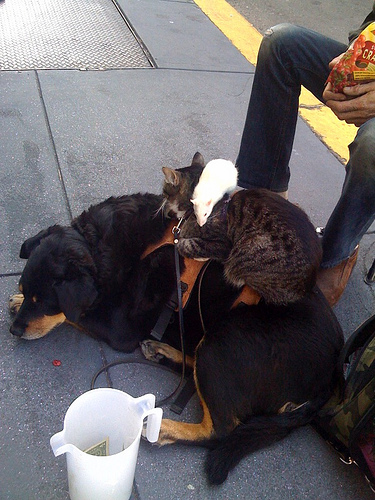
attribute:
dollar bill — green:
[75, 428, 136, 483]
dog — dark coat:
[216, 193, 333, 271]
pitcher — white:
[41, 379, 160, 490]